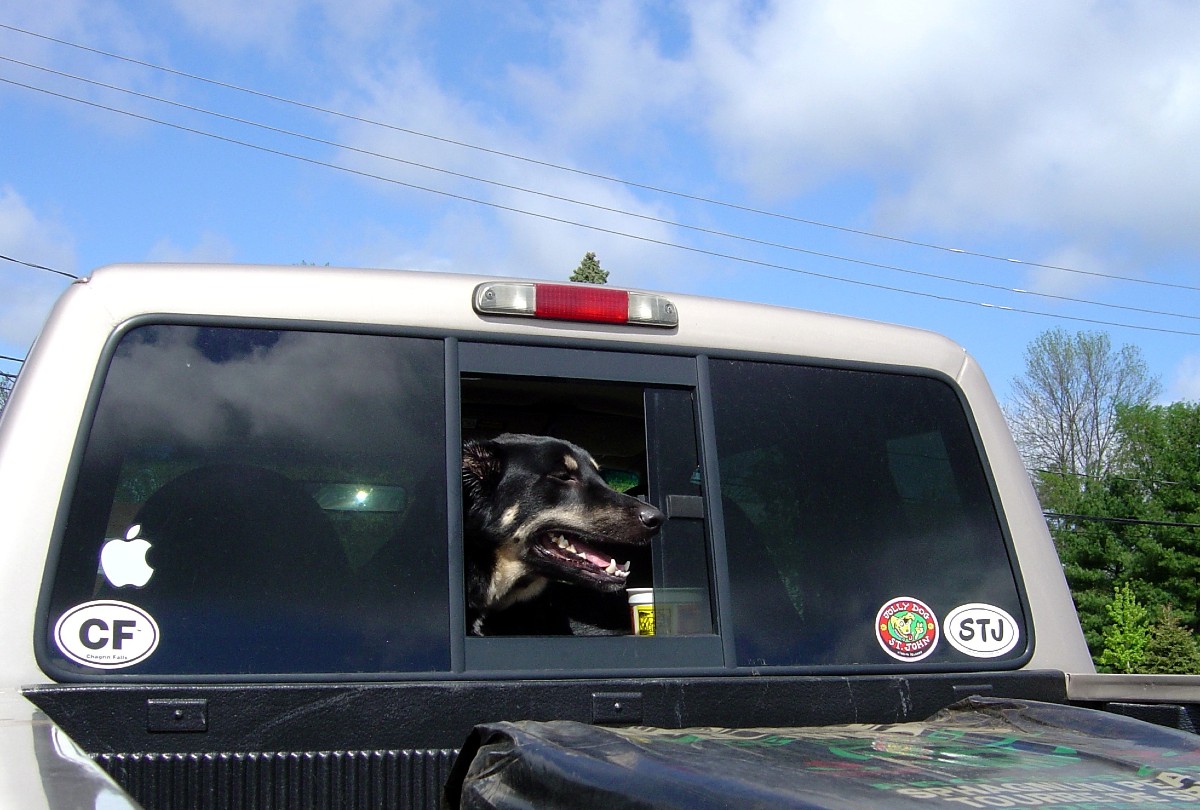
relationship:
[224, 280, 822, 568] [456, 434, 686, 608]
window has dog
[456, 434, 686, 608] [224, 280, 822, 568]
dog in window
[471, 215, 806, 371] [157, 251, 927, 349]
light on top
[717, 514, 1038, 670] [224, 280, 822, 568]
stickers on window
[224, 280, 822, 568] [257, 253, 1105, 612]
window on truck